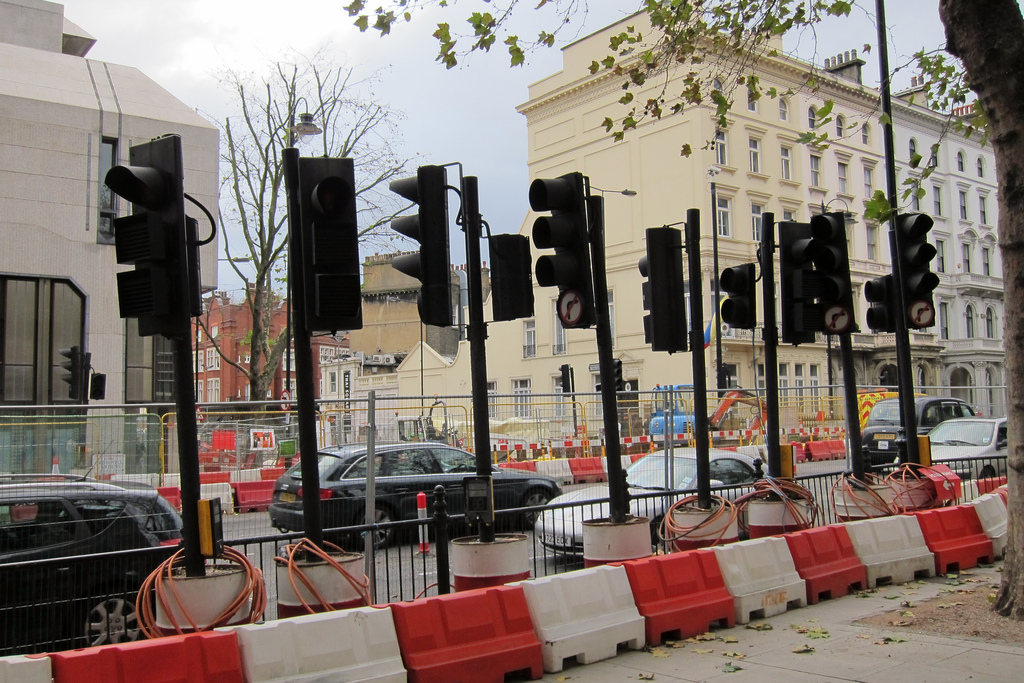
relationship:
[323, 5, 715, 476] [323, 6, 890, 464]
wall of building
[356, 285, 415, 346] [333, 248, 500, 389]
wall of building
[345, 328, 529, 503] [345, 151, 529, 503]
wall of building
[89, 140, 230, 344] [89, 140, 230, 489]
streetlight attached to pole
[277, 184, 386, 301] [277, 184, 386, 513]
streetlight attached to pole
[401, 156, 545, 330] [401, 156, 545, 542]
streetlight attached to pole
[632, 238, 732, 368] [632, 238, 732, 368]
streetlight attached to pole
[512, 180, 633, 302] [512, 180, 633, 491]
streetlight attached to pole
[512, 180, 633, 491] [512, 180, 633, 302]
pole attached to streetlight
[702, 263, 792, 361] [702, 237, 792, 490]
streetlight attached to pole